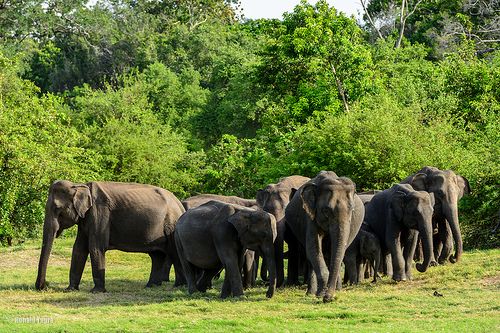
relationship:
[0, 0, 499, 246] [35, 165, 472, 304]
greenery behind elephants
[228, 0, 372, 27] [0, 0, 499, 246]
sky peeking out from trees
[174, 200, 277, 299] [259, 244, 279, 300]
elephant has trunk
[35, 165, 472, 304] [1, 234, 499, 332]
elephants standing on grass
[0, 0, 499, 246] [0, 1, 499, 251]
greenery in background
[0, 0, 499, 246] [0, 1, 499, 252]
trees have leaves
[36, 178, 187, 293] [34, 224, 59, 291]
elephant has trunk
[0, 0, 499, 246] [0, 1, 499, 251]
forest in background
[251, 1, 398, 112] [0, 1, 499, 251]
tree in background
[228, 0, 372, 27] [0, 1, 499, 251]
sky in background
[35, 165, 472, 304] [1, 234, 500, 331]
elephants standing on soil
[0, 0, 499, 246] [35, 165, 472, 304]
trees behind elephants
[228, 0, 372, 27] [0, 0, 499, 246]
sky behind greenery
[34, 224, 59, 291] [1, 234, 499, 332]
trunk touching ground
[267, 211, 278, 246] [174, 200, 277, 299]
light on elephant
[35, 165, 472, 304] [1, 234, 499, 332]
elephants grazing on grass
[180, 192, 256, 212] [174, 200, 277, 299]
elephant behind elephant